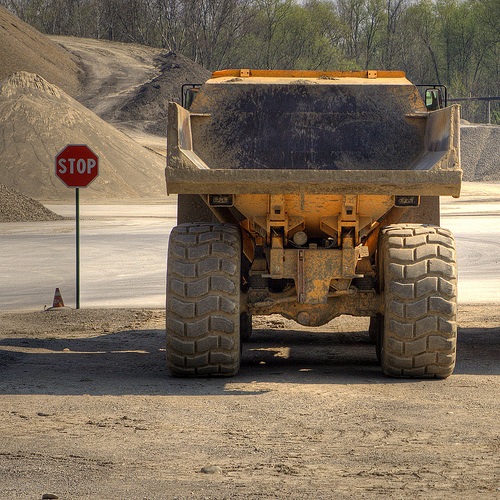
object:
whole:
[55, 143, 100, 310]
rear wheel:
[164, 222, 241, 379]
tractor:
[163, 67, 462, 380]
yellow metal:
[164, 68, 462, 327]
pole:
[75, 188, 80, 309]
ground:
[2, 202, 498, 498]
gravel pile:
[3, 71, 178, 204]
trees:
[4, 2, 499, 130]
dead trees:
[9, 4, 266, 74]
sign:
[55, 143, 100, 189]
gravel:
[0, 71, 58, 124]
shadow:
[0, 326, 500, 397]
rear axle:
[242, 289, 383, 327]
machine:
[165, 65, 462, 378]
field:
[0, 32, 499, 499]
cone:
[53, 287, 65, 307]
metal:
[290, 296, 338, 326]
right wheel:
[375, 223, 458, 379]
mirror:
[425, 88, 442, 108]